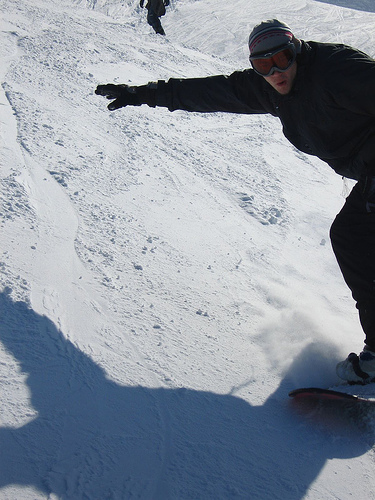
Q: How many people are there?
A: Two.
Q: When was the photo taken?
A: Daytime.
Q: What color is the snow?
A: White.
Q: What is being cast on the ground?
A: A shadow.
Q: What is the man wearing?
A: Snow gear.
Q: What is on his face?
A: Goggles.